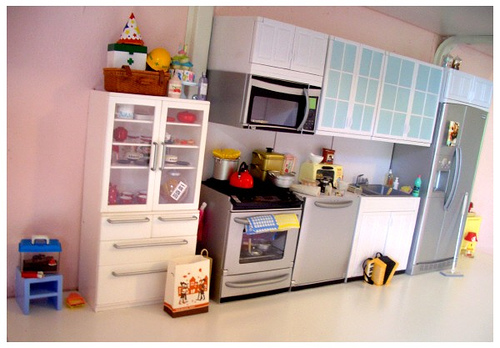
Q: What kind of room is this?
A: It is a kitchen.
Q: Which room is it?
A: It is a kitchen.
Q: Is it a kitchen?
A: Yes, it is a kitchen.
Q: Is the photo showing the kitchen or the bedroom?
A: It is showing the kitchen.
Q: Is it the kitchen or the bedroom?
A: It is the kitchen.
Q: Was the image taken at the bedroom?
A: No, the picture was taken in the kitchen.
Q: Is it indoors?
A: Yes, it is indoors.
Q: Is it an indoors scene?
A: Yes, it is indoors.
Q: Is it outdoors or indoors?
A: It is indoors.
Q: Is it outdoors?
A: No, it is indoors.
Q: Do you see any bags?
A: Yes, there is a bag.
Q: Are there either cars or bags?
A: Yes, there is a bag.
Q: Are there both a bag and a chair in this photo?
A: No, there is a bag but no chairs.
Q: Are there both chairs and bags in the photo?
A: No, there is a bag but no chairs.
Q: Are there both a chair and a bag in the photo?
A: No, there is a bag but no chairs.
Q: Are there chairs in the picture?
A: No, there are no chairs.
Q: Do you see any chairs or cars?
A: No, there are no chairs or cars.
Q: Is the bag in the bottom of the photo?
A: Yes, the bag is in the bottom of the image.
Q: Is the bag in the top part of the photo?
A: No, the bag is in the bottom of the image.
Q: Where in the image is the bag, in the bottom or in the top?
A: The bag is in the bottom of the image.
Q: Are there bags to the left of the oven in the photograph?
A: Yes, there is a bag to the left of the oven.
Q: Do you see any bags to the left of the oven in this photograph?
A: Yes, there is a bag to the left of the oven.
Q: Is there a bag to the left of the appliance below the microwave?
A: Yes, there is a bag to the left of the oven.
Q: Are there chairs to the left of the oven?
A: No, there is a bag to the left of the oven.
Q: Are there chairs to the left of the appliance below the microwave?
A: No, there is a bag to the left of the oven.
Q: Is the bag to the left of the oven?
A: Yes, the bag is to the left of the oven.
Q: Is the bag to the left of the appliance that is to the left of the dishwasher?
A: Yes, the bag is to the left of the oven.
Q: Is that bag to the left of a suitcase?
A: No, the bag is to the left of the oven.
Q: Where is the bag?
A: The bag is on the floor.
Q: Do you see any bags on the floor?
A: Yes, there is a bag on the floor.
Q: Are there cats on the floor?
A: No, there is a bag on the floor.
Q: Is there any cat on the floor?
A: No, there is a bag on the floor.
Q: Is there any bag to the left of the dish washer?
A: Yes, there is a bag to the left of the dish washer.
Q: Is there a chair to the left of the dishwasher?
A: No, there is a bag to the left of the dishwasher.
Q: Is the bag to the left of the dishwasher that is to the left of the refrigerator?
A: Yes, the bag is to the left of the dishwasher.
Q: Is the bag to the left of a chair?
A: No, the bag is to the left of the dishwasher.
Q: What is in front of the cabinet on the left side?
A: The bag is in front of the cabinet.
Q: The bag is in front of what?
A: The bag is in front of the cabinet.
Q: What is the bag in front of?
A: The bag is in front of the cabinet.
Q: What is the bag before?
A: The bag is in front of the cabinet.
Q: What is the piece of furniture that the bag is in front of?
A: The piece of furniture is a cabinet.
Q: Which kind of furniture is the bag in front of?
A: The bag is in front of the cabinet.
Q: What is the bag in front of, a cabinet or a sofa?
A: The bag is in front of a cabinet.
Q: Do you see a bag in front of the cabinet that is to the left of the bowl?
A: Yes, there is a bag in front of the cabinet.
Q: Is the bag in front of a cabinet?
A: Yes, the bag is in front of a cabinet.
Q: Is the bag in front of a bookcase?
A: No, the bag is in front of a cabinet.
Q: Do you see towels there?
A: Yes, there is a towel.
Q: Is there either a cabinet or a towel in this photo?
A: Yes, there is a towel.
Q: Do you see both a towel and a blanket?
A: No, there is a towel but no blankets.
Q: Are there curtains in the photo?
A: No, there are no curtains.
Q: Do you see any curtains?
A: No, there are no curtains.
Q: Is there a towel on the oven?
A: Yes, there is a towel on the oven.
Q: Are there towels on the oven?
A: Yes, there is a towel on the oven.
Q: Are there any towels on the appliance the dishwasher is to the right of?
A: Yes, there is a towel on the oven.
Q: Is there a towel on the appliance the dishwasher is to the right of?
A: Yes, there is a towel on the oven.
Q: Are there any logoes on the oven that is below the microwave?
A: No, there is a towel on the oven.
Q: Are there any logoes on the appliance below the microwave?
A: No, there is a towel on the oven.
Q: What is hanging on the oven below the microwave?
A: The towel is hanging on the oven.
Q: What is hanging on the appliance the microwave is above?
A: The towel is hanging on the oven.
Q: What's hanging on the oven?
A: The towel is hanging on the oven.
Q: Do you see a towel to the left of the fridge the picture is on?
A: Yes, there is a towel to the left of the fridge.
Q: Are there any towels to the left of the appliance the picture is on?
A: Yes, there is a towel to the left of the fridge.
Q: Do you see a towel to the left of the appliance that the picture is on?
A: Yes, there is a towel to the left of the fridge.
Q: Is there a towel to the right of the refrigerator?
A: No, the towel is to the left of the refrigerator.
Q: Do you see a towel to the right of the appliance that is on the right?
A: No, the towel is to the left of the refrigerator.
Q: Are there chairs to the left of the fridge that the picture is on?
A: No, there is a towel to the left of the freezer.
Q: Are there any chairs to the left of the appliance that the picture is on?
A: No, there is a towel to the left of the freezer.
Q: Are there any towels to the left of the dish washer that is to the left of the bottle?
A: Yes, there is a towel to the left of the dishwasher.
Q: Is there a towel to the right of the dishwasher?
A: No, the towel is to the left of the dishwasher.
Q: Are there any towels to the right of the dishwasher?
A: No, the towel is to the left of the dishwasher.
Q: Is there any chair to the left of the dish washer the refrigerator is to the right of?
A: No, there is a towel to the left of the dishwasher.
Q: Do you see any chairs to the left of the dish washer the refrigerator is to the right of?
A: No, there is a towel to the left of the dishwasher.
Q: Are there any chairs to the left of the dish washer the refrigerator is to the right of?
A: No, there is a towel to the left of the dishwasher.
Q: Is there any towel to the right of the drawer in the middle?
A: Yes, there is a towel to the right of the drawer.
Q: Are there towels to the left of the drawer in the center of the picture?
A: No, the towel is to the right of the drawer.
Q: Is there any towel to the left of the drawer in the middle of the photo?
A: No, the towel is to the right of the drawer.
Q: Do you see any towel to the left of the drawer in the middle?
A: No, the towel is to the right of the drawer.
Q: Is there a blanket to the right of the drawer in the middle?
A: No, there is a towel to the right of the drawer.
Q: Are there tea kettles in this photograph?
A: Yes, there is a tea kettle.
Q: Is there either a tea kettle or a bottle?
A: Yes, there is a tea kettle.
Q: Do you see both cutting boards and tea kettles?
A: No, there is a tea kettle but no cutting boards.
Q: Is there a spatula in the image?
A: No, there are no spatulas.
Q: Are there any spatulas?
A: No, there are no spatulas.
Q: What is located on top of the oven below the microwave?
A: The tea kettle is on top of the oven.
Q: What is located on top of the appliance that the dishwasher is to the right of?
A: The tea kettle is on top of the oven.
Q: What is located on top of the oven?
A: The tea kettle is on top of the oven.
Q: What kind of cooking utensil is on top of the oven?
A: The cooking utensil is a tea kettle.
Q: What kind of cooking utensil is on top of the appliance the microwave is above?
A: The cooking utensil is a tea kettle.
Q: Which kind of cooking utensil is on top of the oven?
A: The cooking utensil is a tea kettle.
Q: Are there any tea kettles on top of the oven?
A: Yes, there is a tea kettle on top of the oven.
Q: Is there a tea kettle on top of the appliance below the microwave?
A: Yes, there is a tea kettle on top of the oven.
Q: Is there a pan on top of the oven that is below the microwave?
A: No, there is a tea kettle on top of the oven.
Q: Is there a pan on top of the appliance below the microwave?
A: No, there is a tea kettle on top of the oven.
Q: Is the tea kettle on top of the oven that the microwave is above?
A: Yes, the tea kettle is on top of the oven.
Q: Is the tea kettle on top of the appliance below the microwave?
A: Yes, the tea kettle is on top of the oven.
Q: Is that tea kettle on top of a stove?
A: No, the tea kettle is on top of the oven.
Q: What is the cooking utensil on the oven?
A: The cooking utensil is a tea kettle.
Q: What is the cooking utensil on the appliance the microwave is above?
A: The cooking utensil is a tea kettle.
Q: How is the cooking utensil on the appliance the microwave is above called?
A: The cooking utensil is a tea kettle.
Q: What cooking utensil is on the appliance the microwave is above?
A: The cooking utensil is a tea kettle.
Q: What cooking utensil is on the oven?
A: The cooking utensil is a tea kettle.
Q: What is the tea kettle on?
A: The tea kettle is on the oven.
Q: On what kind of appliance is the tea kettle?
A: The tea kettle is on the oven.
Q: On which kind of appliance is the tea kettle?
A: The tea kettle is on the oven.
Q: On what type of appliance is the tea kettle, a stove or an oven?
A: The tea kettle is on an oven.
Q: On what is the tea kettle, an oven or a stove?
A: The tea kettle is on an oven.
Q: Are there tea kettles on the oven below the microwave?
A: Yes, there is a tea kettle on the oven.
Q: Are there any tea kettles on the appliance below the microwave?
A: Yes, there is a tea kettle on the oven.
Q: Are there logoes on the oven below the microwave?
A: No, there is a tea kettle on the oven.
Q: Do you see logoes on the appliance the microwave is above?
A: No, there is a tea kettle on the oven.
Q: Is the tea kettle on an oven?
A: Yes, the tea kettle is on an oven.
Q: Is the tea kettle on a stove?
A: No, the tea kettle is on an oven.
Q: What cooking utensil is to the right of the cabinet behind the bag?
A: The cooking utensil is a tea kettle.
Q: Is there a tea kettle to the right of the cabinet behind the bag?
A: Yes, there is a tea kettle to the right of the cabinet.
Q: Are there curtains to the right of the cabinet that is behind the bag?
A: No, there is a tea kettle to the right of the cabinet.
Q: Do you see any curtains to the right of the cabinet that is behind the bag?
A: No, there is a tea kettle to the right of the cabinet.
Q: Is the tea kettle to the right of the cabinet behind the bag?
A: Yes, the tea kettle is to the right of the cabinet.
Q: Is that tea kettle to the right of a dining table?
A: No, the tea kettle is to the right of the cabinet.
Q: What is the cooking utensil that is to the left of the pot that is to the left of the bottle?
A: The cooking utensil is a tea kettle.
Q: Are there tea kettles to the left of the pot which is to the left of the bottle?
A: Yes, there is a tea kettle to the left of the pot.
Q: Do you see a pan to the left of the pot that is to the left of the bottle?
A: No, there is a tea kettle to the left of the pot.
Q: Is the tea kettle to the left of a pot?
A: Yes, the tea kettle is to the left of a pot.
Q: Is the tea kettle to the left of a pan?
A: No, the tea kettle is to the left of a pot.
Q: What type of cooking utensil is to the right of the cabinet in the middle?
A: The cooking utensil is a tea kettle.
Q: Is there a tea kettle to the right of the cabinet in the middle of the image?
A: Yes, there is a tea kettle to the right of the cabinet.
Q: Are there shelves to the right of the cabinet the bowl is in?
A: No, there is a tea kettle to the right of the cabinet.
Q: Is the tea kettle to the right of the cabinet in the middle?
A: Yes, the tea kettle is to the right of the cabinet.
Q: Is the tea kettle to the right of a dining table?
A: No, the tea kettle is to the right of the cabinet.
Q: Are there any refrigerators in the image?
A: Yes, there is a refrigerator.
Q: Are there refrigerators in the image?
A: Yes, there is a refrigerator.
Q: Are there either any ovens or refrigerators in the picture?
A: Yes, there is a refrigerator.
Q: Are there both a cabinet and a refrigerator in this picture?
A: Yes, there are both a refrigerator and a cabinet.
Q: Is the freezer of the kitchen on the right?
A: Yes, the freezer is on the right of the image.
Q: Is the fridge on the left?
A: No, the fridge is on the right of the image.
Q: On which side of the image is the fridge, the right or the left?
A: The fridge is on the right of the image.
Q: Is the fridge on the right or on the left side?
A: The fridge is on the right of the image.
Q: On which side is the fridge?
A: The fridge is on the right of the image.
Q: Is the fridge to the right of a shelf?
A: No, the fridge is to the right of the towel.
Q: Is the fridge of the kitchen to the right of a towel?
A: Yes, the fridge is to the right of a towel.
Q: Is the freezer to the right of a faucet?
A: No, the freezer is to the right of a towel.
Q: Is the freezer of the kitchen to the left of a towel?
A: No, the refrigerator is to the right of a towel.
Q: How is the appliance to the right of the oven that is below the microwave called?
A: The appliance is a refrigerator.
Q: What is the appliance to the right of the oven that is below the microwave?
A: The appliance is a refrigerator.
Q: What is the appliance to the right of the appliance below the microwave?
A: The appliance is a refrigerator.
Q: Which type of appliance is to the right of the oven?
A: The appliance is a refrigerator.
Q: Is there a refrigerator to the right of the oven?
A: Yes, there is a refrigerator to the right of the oven.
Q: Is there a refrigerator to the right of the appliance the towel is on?
A: Yes, there is a refrigerator to the right of the oven.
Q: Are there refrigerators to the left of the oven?
A: No, the refrigerator is to the right of the oven.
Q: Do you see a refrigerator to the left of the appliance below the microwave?
A: No, the refrigerator is to the right of the oven.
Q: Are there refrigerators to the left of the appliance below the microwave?
A: No, the refrigerator is to the right of the oven.